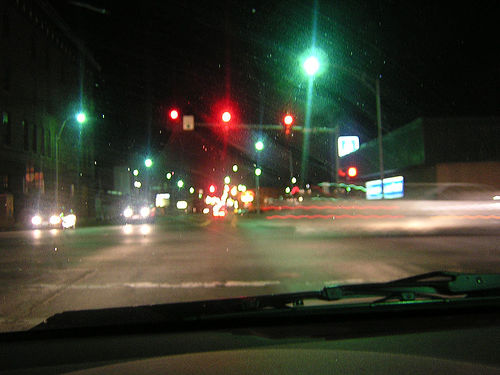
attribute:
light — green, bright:
[297, 49, 326, 79]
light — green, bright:
[70, 110, 92, 128]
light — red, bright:
[211, 100, 242, 131]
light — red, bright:
[167, 108, 180, 121]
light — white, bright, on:
[141, 207, 152, 217]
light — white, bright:
[50, 215, 60, 225]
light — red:
[283, 114, 295, 126]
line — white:
[18, 280, 369, 288]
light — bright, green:
[255, 140, 265, 151]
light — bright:
[255, 167, 262, 176]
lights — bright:
[203, 176, 254, 216]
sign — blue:
[365, 175, 404, 199]